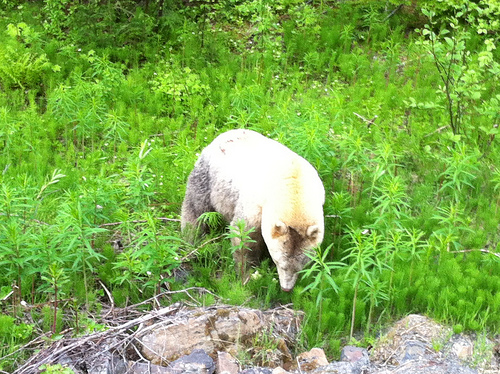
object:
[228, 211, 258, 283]
leg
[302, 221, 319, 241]
ear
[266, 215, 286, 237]
ear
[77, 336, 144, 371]
rock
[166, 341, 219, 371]
rock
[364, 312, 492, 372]
rock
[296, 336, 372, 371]
rock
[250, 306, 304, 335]
rock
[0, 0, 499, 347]
grass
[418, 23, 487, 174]
plant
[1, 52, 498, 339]
tall grass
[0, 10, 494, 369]
plants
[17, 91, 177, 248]
field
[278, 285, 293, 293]
nose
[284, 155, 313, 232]
stripe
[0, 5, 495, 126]
forest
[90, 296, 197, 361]
sticks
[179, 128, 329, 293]
bear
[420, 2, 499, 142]
tree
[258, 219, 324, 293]
head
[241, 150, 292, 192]
fur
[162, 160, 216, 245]
leg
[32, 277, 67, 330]
twigs